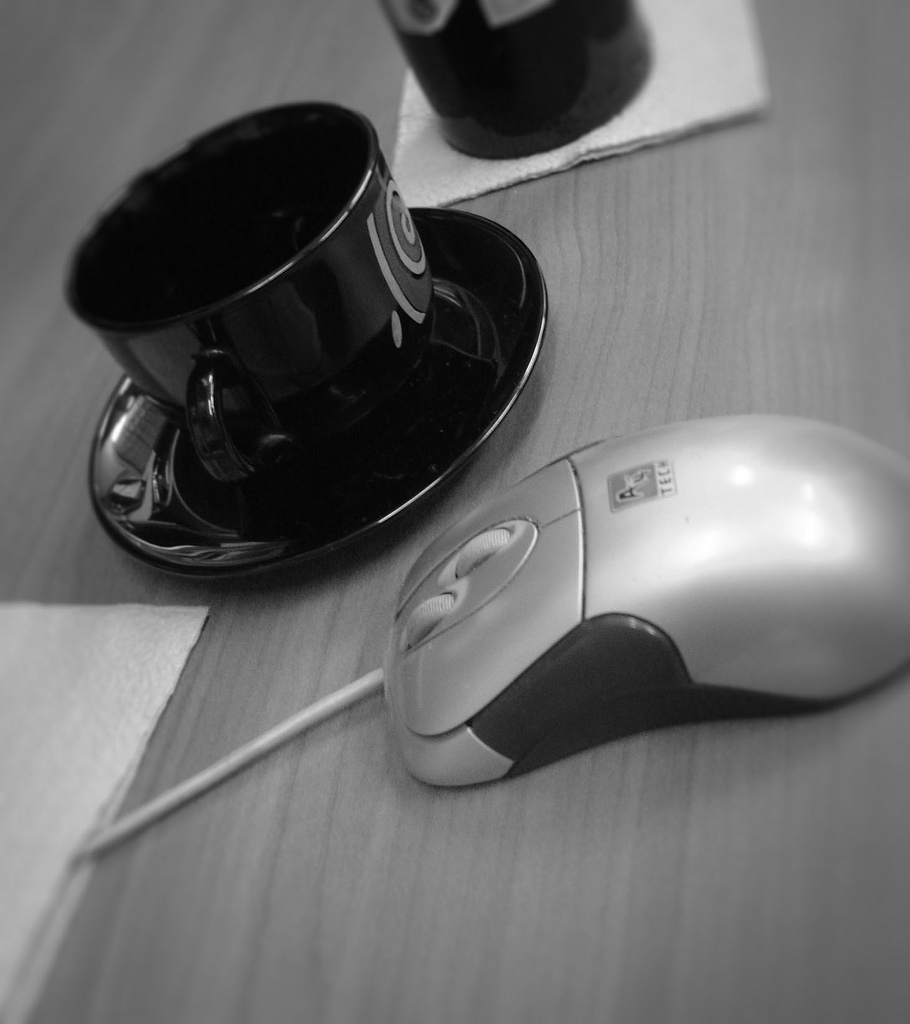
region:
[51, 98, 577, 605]
A black cup and a saucer.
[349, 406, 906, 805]
A silver computer mouse.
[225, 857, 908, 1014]
A light-colored wooden table.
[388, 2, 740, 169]
A black cup on napkin.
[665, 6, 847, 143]
The edge of a white paper towel.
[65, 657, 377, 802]
The cord of computer mouse.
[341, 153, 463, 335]
A circular design on cup.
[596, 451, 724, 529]
Logo of the computer mouse.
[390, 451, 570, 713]
Buttons of the computer mouse.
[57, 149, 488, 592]
Black cup and saucer.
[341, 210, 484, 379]
Design, shaped like bulls-eye, on cup.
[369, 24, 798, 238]
Napkin and tall, black cup.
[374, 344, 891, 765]
A silver and black mouse.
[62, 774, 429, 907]
Part of a white cord.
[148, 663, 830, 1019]
A pale, wooden surface.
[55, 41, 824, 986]
A view that tilts upwards.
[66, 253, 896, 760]
A mouse that appears bigger than the adjacent cup and saucer.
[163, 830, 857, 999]
Horizontal lines from wood-grain.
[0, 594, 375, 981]
The corner of a second napkin, or paper towel.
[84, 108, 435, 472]
Shiny black cup, with target design.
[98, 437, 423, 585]
Black saucer, with white etching on rim.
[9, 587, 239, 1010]
A corner of paper toweling, or napkin.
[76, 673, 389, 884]
White, or grey mouse cord.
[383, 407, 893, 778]
Silver and black mouse.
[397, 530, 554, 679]
Rounded control knobs.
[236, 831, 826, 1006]
Pale wood with even grain.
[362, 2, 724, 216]
Second black cup with unclear design.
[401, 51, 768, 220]
Cup resting on napkin or toweling.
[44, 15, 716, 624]
Cups reveal slant of overall picture.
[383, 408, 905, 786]
optical mouse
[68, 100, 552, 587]
black coffee cup with black saucer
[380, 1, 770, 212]
black coffee cup sitting on top of a white napkin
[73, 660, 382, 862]
grey wire running to optical mouse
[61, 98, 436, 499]
black coffee cup with round circle design on it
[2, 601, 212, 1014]
white napkin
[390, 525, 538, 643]
two scroll wheel on optical mouse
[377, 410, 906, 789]
right handed black and grey optical mouse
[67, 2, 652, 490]
two black coffee cups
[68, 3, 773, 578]
two black coffee cups on on a saucer and one on a white napkin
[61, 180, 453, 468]
The mug is black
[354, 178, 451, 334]
mug's print is circular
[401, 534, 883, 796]
The mouse is on the table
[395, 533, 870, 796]
The mouse is silver and black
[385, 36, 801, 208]
Tissue is under a mug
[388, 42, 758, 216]
The tissue is white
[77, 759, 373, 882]
Mouse's cord is white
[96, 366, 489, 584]
A small plate under the mug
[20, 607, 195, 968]
Tissue is beside the mug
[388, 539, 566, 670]
there are two rollers on the mouse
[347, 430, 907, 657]
A wired gray mouse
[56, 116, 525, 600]
A black coffee cup atop a saucer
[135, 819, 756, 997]
Wooden desk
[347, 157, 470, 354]
Logo consisting of several rings on coffee cup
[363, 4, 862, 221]
Drink placed atop a section of paper towel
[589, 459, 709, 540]
Logo from manufacturing company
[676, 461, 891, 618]
Glare against mouse from overhead lights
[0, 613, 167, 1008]
Paper towel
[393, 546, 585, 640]
Spin rollers atop mouse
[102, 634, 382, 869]
wire connecting mouse to computer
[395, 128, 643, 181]
white napkin beneath cup